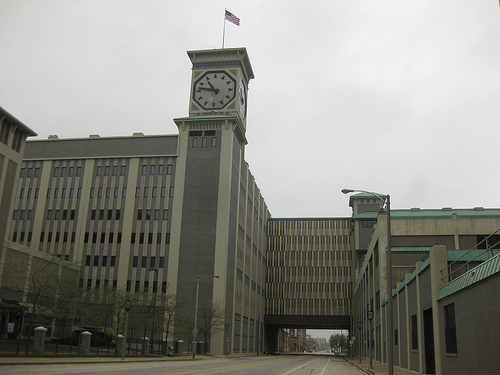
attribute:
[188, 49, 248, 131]
clock — big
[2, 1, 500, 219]
sky — grey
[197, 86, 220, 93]
hand — black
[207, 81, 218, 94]
hand — black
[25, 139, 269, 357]
building — tall, gray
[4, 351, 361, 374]
road — black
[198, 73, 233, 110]
numbers — triangles